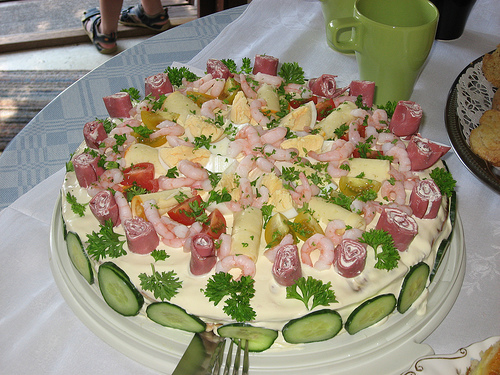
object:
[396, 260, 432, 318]
cucumber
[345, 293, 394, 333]
cucumber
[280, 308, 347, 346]
cucumber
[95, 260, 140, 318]
cucumber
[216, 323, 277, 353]
cucumbers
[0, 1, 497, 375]
table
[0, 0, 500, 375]
tablecloth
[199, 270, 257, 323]
leaf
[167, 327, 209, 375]
knife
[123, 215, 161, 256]
meat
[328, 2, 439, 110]
coffee cup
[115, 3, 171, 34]
sandal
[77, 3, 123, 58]
feet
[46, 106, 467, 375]
tray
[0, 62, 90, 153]
rug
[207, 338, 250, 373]
fork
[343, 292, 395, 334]
cucumbers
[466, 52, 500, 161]
cookies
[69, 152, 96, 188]
ham slices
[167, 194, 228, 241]
tomatoes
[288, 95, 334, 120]
tomatoes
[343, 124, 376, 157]
tomatoes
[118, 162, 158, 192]
tomato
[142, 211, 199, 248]
shrimps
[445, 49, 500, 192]
silver plate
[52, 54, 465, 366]
cake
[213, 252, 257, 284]
peeled shrimp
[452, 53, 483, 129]
doily